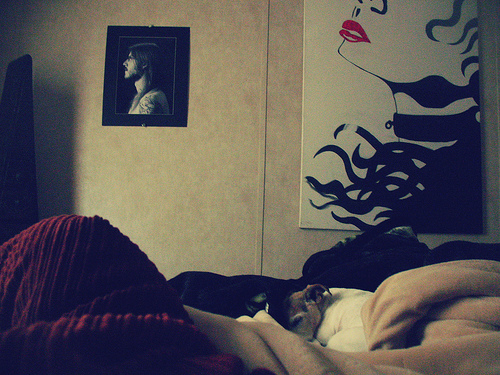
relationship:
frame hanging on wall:
[101, 25, 192, 128] [2, 0, 300, 280]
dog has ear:
[284, 282, 330, 344] [305, 281, 332, 298]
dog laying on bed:
[165, 270, 316, 329] [2, 284, 498, 374]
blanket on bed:
[0, 214, 278, 374] [1, 264, 496, 374]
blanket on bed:
[233, 315, 342, 359] [2, 284, 498, 374]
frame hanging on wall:
[101, 25, 192, 128] [197, 2, 497, 236]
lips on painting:
[339, 19, 371, 43] [299, 0, 487, 236]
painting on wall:
[299, 0, 487, 236] [9, 6, 493, 280]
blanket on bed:
[0, 214, 278, 374] [0, 212, 499, 373]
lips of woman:
[336, 17, 376, 46] [303, 0, 485, 232]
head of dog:
[245, 281, 333, 342] [165, 266, 332, 344]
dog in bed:
[284, 282, 378, 355] [0, 212, 499, 373]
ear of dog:
[139, 61, 148, 68] [279, 280, 379, 357]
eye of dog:
[299, 301, 310, 317] [165, 270, 316, 329]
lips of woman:
[339, 19, 371, 43] [303, 0, 485, 232]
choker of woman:
[385, 107, 477, 144] [303, 0, 485, 232]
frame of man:
[101, 25, 192, 128] [124, 42, 166, 114]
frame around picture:
[99, 21, 194, 135] [118, 36, 175, 116]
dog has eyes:
[165, 266, 332, 344] [288, 288, 317, 335]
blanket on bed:
[5, 209, 245, 370] [33, 196, 499, 373]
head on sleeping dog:
[283, 284, 333, 341] [165, 262, 339, 348]